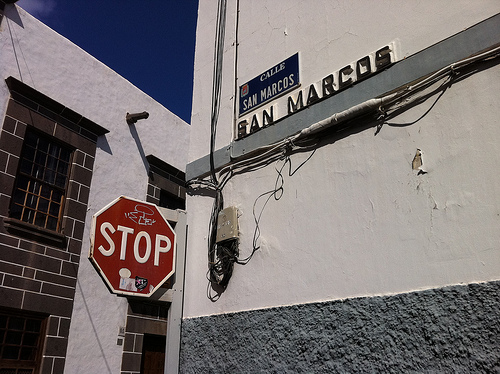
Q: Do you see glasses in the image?
A: No, there are no glasses.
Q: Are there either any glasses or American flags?
A: No, there are no glasses or American flags.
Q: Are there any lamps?
A: No, there are no lamps.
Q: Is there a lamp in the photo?
A: No, there are no lamps.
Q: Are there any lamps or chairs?
A: No, there are no lamps or chairs.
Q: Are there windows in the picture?
A: Yes, there is a window.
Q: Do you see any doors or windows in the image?
A: Yes, there is a window.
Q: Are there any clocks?
A: No, there are no clocks.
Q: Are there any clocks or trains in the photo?
A: No, there are no clocks or trains.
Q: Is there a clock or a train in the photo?
A: No, there are no clocks or trains.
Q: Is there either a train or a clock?
A: No, there are no clocks or trains.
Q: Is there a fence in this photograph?
A: No, there are no fences.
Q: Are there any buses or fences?
A: No, there are no fences or buses.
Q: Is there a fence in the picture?
A: No, there are no fences.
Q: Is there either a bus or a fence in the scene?
A: No, there are no fences or buses.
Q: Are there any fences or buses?
A: No, there are no fences or buses.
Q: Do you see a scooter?
A: No, there are no scooters.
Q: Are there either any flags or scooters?
A: No, there are no scooters or flags.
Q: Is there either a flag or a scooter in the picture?
A: No, there are no scooters or flags.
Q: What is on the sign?
A: The graffiti is on the sign.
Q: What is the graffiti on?
A: The graffiti is on the sign.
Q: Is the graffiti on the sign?
A: Yes, the graffiti is on the sign.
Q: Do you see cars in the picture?
A: No, there are no cars.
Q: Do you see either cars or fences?
A: No, there are no cars or fences.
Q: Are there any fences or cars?
A: No, there are no cars or fences.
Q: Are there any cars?
A: No, there are no cars.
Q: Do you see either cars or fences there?
A: No, there are no cars or fences.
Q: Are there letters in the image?
A: Yes, there are letters.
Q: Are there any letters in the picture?
A: Yes, there are letters.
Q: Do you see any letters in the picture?
A: Yes, there are letters.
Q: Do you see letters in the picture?
A: Yes, there are letters.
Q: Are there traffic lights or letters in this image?
A: Yes, there are letters.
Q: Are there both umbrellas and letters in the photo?
A: No, there are letters but no umbrellas.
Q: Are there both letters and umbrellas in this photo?
A: No, there are letters but no umbrellas.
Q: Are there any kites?
A: No, there are no kites.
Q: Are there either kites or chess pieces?
A: No, there are no kites or chess pieces.